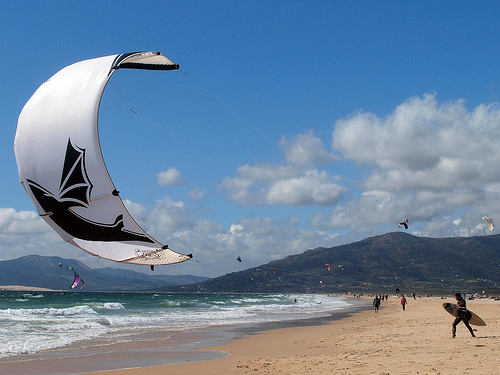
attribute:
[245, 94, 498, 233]
cloud — fluffy, little, white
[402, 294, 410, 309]
woman — walking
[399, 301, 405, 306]
pants — black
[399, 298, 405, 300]
shirt — red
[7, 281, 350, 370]
sea — green, gorgeous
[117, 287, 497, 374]
shore — brown, wide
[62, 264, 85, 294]
windsail — magenta, white, black, pink, billowing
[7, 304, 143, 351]
waves — tiny, white crested, small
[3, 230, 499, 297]
hills — blue, green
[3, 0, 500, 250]
sky — cloudy, grey, blue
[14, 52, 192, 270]
kite — large, white, black, decorative, flying, whiet, red, billowing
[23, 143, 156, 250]
image — black, smiling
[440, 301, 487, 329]
surfboard — yellow, long, pointed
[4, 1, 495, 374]
beach — partly cloudy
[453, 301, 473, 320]
wetsuit — black